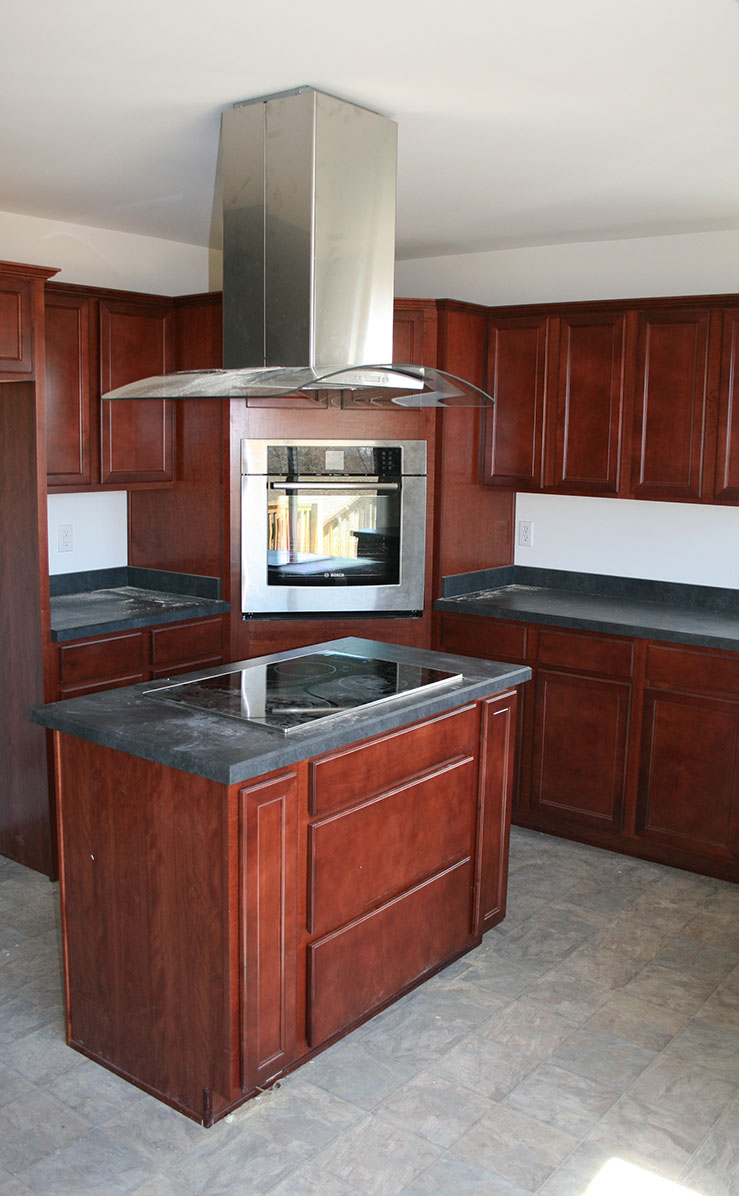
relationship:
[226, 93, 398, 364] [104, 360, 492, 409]
pipe above hood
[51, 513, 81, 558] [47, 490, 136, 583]
outlet on wall